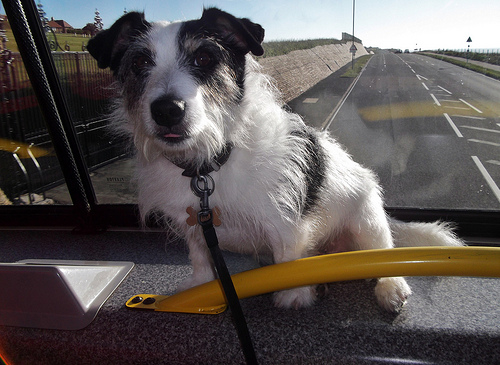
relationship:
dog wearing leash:
[85, 5, 473, 314] [140, 168, 330, 363]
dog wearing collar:
[85, 5, 473, 314] [165, 143, 234, 178]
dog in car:
[118, 35, 265, 150] [0, 0, 497, 364]